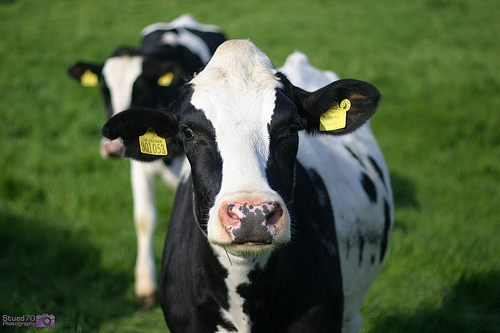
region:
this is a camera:
[23, 311, 61, 331]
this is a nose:
[215, 192, 292, 251]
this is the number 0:
[26, 309, 42, 327]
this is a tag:
[315, 87, 360, 142]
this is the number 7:
[20, 310, 31, 324]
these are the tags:
[67, 55, 368, 164]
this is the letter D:
[17, 312, 27, 324]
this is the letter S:
[0, 313, 11, 325]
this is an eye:
[172, 123, 204, 147]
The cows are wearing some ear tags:
[30, 1, 475, 321]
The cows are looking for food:
[30, 5, 490, 315]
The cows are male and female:
[50, 0, 495, 305]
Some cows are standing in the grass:
[20, 10, 495, 315]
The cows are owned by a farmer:
[30, 10, 485, 315]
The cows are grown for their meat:
[31, 10, 491, 327]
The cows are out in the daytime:
[40, 16, 460, 331]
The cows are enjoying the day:
[49, 15, 499, 311]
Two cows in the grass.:
[63, 13, 396, 330]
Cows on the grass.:
[64, 12, 396, 332]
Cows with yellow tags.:
[65, 10, 396, 332]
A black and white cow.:
[99, 35, 396, 330]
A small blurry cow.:
[64, 12, 229, 309]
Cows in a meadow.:
[65, 11, 395, 331]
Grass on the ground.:
[1, 0, 498, 330]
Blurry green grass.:
[1, 1, 498, 331]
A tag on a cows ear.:
[137, 128, 169, 158]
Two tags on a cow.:
[139, 95, 351, 159]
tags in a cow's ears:
[132, 94, 362, 160]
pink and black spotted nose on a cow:
[221, 191, 282, 250]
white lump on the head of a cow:
[210, 34, 263, 71]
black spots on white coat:
[342, 141, 394, 262]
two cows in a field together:
[68, 10, 402, 327]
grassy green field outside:
[0, 5, 497, 326]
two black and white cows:
[61, 7, 392, 330]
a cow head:
[102, 30, 379, 295]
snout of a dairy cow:
[198, 190, 296, 257]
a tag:
[316, 107, 352, 131]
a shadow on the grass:
[26, 241, 96, 291]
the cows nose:
[216, 191, 287, 251]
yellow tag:
[137, 136, 167, 158]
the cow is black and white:
[302, 174, 386, 224]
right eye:
[184, 127, 204, 145]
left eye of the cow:
[274, 124, 291, 147]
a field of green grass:
[431, 32, 483, 194]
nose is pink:
[221, 199, 251, 228]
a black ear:
[308, 83, 377, 136]